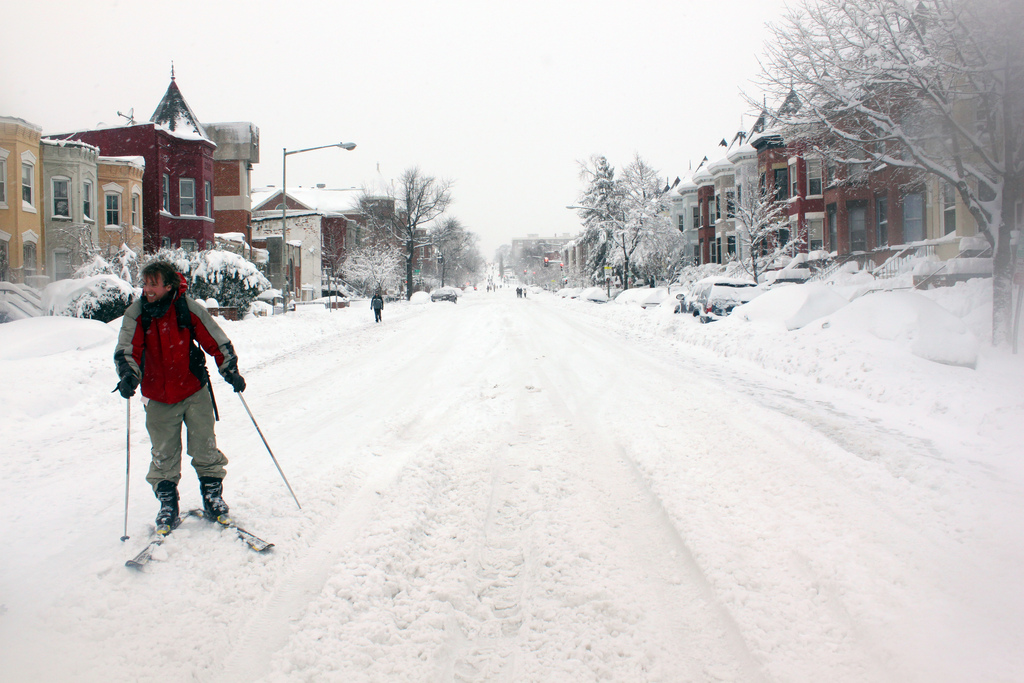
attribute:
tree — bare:
[737, 10, 1022, 342]